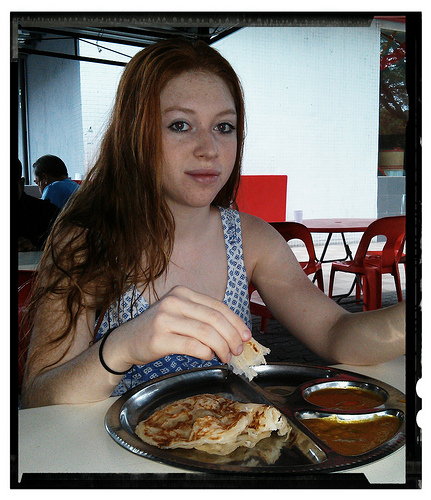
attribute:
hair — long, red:
[20, 36, 246, 369]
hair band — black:
[98, 328, 132, 377]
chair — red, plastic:
[328, 215, 405, 310]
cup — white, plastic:
[292, 208, 306, 223]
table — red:
[296, 218, 375, 263]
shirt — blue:
[40, 177, 80, 206]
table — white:
[19, 356, 406, 483]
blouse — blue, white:
[96, 205, 252, 404]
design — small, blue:
[231, 298, 238, 307]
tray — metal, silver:
[105, 360, 407, 472]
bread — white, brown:
[133, 393, 292, 455]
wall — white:
[80, 28, 381, 245]